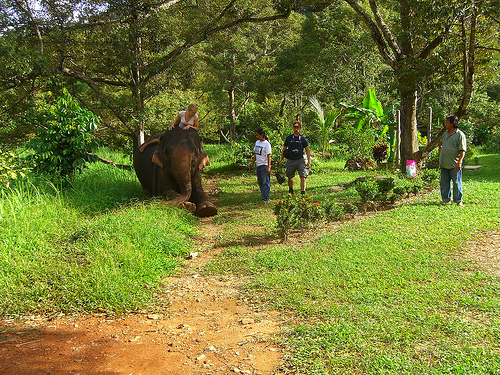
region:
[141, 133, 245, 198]
Elephant in the woods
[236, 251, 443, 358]
Green grass on the ground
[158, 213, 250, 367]
Dirt path in the woods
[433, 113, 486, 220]
Man standing with a green shirt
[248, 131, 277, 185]
Man standing with a white shirt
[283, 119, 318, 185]
Man standing in shorts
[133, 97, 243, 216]
Woman riding an elephant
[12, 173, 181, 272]
Tall, green grass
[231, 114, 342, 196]
Men watching a woman ride an elephant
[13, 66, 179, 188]
Trees in a forset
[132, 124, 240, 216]
a brown envelope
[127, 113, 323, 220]
to people standing next to an elephant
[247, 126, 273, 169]
a person wearing a white tshirt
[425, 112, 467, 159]
a man with his hand on his hip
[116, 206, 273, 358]
a dirt path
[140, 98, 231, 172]
a woman sitting on an elephant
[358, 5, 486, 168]
an odd shape tree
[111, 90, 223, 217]
an elephant resting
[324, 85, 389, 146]
bright green plants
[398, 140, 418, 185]
bag leaning against tree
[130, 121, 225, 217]
elephant kneeling towards the ground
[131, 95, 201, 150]
woman climbing onto elephant's back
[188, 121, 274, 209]
woman looking towards elephant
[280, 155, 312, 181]
man is wearing shorts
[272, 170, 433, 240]
flowering plants set in a row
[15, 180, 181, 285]
tall grass near elephant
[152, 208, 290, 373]
dirt path through the grass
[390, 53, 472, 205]
man near a large tree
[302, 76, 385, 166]
plants with large leaves in the distance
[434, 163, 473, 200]
man wearing blue jeans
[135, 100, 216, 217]
a woman riding an elephant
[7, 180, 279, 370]
a narrow walking trail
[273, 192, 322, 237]
pretty red flowers growing in the wild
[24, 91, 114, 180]
a small tree growing in the wilderness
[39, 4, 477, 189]
trees of all sizes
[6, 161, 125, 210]
tall green grass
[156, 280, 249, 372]
rocks embedded in a foot path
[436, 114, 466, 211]
a man standing, looking to his right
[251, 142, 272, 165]
a woman's white t-shirt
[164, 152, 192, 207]
an elephant's trunk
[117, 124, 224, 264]
This is an elephant.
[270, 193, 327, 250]
This is a plant with flowers.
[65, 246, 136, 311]
This is a section of grass.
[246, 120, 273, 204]
This is a woman.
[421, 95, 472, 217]
This is a man.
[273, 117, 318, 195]
This is a man in shorts.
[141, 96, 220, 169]
This woman is on an elephant.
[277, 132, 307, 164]
This is a shirt.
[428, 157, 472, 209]
These are blue jeans.